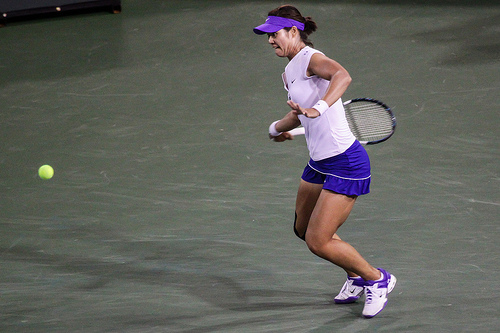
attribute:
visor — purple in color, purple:
[245, 16, 304, 34]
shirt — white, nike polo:
[275, 46, 357, 164]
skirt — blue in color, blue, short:
[301, 139, 375, 194]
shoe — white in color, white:
[358, 267, 403, 318]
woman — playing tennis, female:
[252, 4, 404, 318]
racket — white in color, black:
[277, 94, 397, 148]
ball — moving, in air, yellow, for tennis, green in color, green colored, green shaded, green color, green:
[35, 161, 57, 181]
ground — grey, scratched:
[4, 0, 498, 332]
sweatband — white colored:
[312, 98, 329, 115]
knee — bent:
[299, 227, 346, 255]